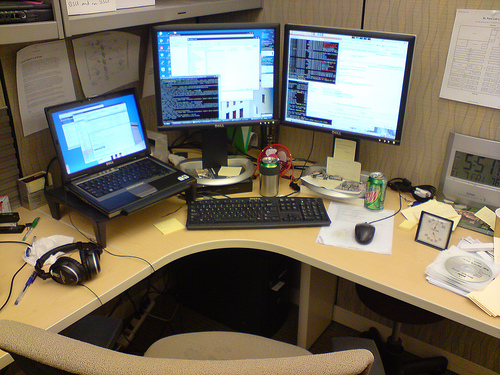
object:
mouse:
[355, 223, 376, 245]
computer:
[150, 21, 280, 187]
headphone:
[34, 241, 103, 286]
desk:
[0, 149, 499, 375]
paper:
[437, 8, 500, 110]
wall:
[0, 17, 194, 210]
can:
[364, 171, 388, 210]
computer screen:
[285, 30, 409, 140]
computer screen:
[157, 29, 274, 126]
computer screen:
[52, 94, 147, 175]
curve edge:
[155, 239, 304, 272]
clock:
[436, 131, 500, 210]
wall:
[197, 0, 500, 195]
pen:
[14, 268, 37, 305]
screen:
[52, 94, 147, 175]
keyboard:
[186, 196, 332, 230]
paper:
[316, 198, 395, 255]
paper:
[424, 236, 500, 299]